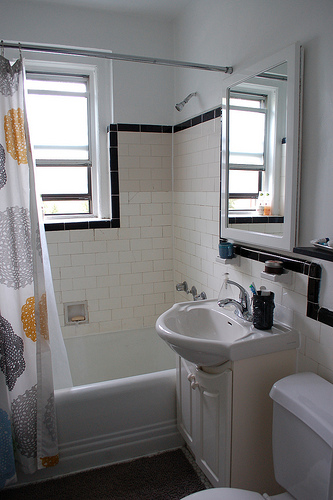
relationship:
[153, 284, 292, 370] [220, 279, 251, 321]
sink has faucet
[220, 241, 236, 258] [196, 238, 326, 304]
cup on bathroom ledge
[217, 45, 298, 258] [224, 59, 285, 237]
frame on mirror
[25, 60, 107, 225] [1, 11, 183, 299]
window in wall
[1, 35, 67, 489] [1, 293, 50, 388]
curtain has circles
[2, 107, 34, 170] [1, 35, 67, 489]
circle in curtain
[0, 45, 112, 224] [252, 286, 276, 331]
window in cup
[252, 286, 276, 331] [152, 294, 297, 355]
cup on sink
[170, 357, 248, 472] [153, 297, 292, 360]
cabinet under sink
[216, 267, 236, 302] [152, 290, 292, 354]
sopa dispenser on sink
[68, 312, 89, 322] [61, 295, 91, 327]
soap on dispenser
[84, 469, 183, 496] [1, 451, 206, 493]
rug on floor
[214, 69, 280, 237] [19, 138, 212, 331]
mirror on wall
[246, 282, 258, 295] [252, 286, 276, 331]
toothbrushes in cup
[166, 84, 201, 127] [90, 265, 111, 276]
shower of tile